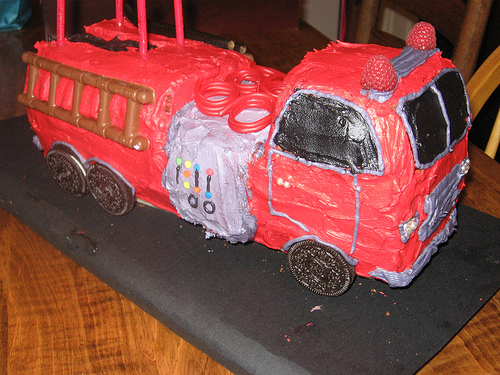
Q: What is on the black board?
A: Cake.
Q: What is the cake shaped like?
A: Fire truck.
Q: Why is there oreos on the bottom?
A: To look like wheels.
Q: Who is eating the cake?
A: Birthday guests.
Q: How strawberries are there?
A: Two.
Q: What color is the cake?
A: Red.